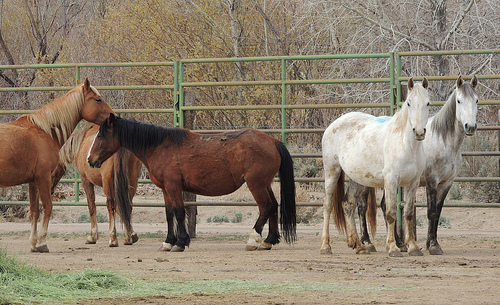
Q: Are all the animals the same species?
A: Yes, all the animals are horses.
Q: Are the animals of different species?
A: No, all the animals are horses.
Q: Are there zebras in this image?
A: No, there are no zebras.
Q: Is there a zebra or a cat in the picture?
A: No, there are no zebras or cats.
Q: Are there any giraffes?
A: No, there are no giraffes.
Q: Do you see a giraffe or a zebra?
A: No, there are no giraffes or zebras.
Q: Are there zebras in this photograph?
A: No, there are no zebras.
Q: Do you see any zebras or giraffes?
A: No, there are no zebras or giraffes.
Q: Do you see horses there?
A: Yes, there is a horse.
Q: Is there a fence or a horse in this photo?
A: Yes, there is a horse.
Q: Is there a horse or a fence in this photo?
A: Yes, there is a horse.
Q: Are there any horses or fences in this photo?
A: Yes, there is a horse.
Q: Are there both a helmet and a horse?
A: No, there is a horse but no helmets.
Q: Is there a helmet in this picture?
A: No, there are no helmets.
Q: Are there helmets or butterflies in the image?
A: No, there are no helmets or butterflies.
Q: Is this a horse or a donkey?
A: This is a horse.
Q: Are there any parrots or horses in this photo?
A: Yes, there is a horse.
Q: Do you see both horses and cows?
A: No, there is a horse but no cows.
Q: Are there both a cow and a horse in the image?
A: No, there is a horse but no cows.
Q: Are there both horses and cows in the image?
A: No, there is a horse but no cows.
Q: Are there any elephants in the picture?
A: No, there are no elephants.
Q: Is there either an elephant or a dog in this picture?
A: No, there are no elephants or dogs.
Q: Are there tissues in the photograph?
A: No, there are no tissues.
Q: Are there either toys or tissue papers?
A: No, there are no tissue papers or toys.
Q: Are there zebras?
A: No, there are no zebras.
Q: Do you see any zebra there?
A: No, there are no zebras.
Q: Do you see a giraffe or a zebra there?
A: No, there are no zebras or giraffes.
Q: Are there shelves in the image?
A: No, there are no shelves.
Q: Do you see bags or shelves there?
A: No, there are no shelves or bags.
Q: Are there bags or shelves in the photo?
A: No, there are no shelves or bags.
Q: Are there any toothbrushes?
A: No, there are no toothbrushes.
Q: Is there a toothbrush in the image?
A: No, there are no toothbrushes.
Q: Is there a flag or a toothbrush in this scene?
A: No, there are no toothbrushes or flags.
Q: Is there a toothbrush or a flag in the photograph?
A: No, there are no toothbrushes or flags.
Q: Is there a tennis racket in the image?
A: No, there are no rackets.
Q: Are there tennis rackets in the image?
A: No, there are no tennis rackets.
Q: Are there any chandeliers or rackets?
A: No, there are no rackets or chandeliers.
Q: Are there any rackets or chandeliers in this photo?
A: No, there are no rackets or chandeliers.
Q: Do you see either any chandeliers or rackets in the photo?
A: No, there are no rackets or chandeliers.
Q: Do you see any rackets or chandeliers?
A: No, there are no rackets or chandeliers.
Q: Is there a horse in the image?
A: Yes, there is a horse.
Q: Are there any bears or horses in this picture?
A: Yes, there is a horse.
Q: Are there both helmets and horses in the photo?
A: No, there is a horse but no helmets.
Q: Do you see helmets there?
A: No, there are no helmets.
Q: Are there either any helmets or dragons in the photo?
A: No, there are no helmets or dragons.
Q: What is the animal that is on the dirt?
A: The animal is a horse.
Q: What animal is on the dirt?
A: The animal is a horse.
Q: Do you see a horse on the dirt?
A: Yes, there is a horse on the dirt.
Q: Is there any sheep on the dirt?
A: No, there is a horse on the dirt.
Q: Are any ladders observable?
A: No, there are no ladders.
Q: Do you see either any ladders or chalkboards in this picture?
A: No, there are no ladders or chalkboards.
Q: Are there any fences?
A: Yes, there is a fence.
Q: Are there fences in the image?
A: Yes, there is a fence.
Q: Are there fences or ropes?
A: Yes, there is a fence.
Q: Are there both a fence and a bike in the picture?
A: No, there is a fence but no bikes.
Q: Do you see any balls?
A: No, there are no balls.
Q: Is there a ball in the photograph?
A: No, there are no balls.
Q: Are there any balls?
A: No, there are no balls.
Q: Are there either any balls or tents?
A: No, there are no balls or tents.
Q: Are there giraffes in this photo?
A: No, there are no giraffes.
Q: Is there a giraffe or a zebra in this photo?
A: No, there are no giraffes or zebras.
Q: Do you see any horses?
A: Yes, there is a horse.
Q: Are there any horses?
A: Yes, there is a horse.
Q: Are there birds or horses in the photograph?
A: Yes, there is a horse.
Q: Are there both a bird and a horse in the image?
A: No, there is a horse but no birds.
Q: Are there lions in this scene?
A: No, there are no lions.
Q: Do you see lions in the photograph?
A: No, there are no lions.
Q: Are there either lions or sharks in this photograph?
A: No, there are no lions or sharks.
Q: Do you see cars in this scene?
A: No, there are no cars.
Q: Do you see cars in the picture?
A: No, there are no cars.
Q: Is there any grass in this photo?
A: Yes, there is grass.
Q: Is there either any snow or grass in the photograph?
A: Yes, there is grass.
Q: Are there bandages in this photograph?
A: No, there are no bandages.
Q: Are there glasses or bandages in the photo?
A: No, there are no bandages or glasses.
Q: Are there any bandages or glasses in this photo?
A: No, there are no bandages or glasses.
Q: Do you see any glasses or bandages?
A: No, there are no bandages or glasses.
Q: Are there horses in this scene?
A: Yes, there is a horse.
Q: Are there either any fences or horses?
A: Yes, there is a horse.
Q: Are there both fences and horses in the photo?
A: Yes, there are both a horse and a fence.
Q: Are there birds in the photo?
A: No, there are no birds.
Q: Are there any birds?
A: No, there are no birds.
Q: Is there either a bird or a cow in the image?
A: No, there are no birds or cows.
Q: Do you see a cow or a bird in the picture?
A: No, there are no birds or cows.